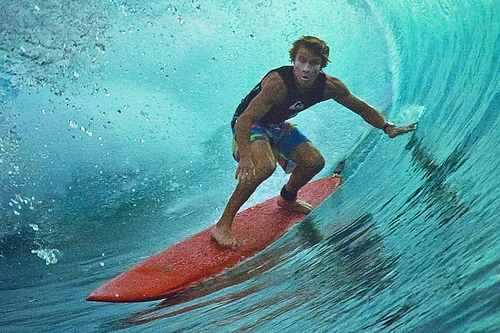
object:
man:
[210, 35, 419, 251]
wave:
[1, 0, 499, 333]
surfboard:
[85, 174, 343, 303]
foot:
[208, 225, 240, 250]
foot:
[275, 195, 313, 214]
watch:
[380, 121, 396, 134]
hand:
[383, 121, 420, 139]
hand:
[234, 157, 257, 184]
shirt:
[231, 65, 326, 129]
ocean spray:
[1, 0, 258, 265]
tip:
[84, 290, 102, 301]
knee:
[299, 155, 326, 170]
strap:
[381, 124, 387, 131]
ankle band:
[280, 183, 298, 202]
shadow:
[290, 207, 415, 326]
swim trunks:
[230, 120, 313, 174]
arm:
[332, 77, 393, 132]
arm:
[233, 71, 288, 157]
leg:
[271, 122, 326, 198]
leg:
[215, 123, 278, 226]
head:
[287, 34, 332, 89]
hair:
[287, 34, 333, 74]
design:
[287, 100, 305, 111]